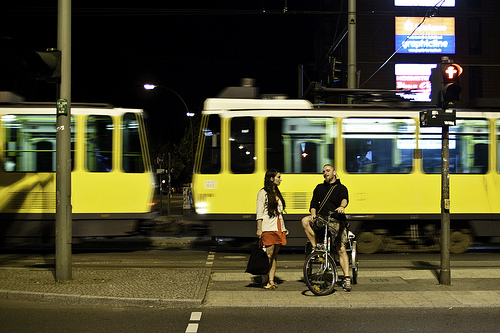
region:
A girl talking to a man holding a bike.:
[245, 163, 282, 290]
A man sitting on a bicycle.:
[300, 163, 353, 295]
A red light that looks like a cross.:
[442, 58, 462, 80]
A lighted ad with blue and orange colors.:
[392, 14, 460, 52]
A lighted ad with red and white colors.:
[390, 60, 452, 97]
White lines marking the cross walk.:
[183, 233, 223, 328]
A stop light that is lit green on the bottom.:
[327, 52, 344, 97]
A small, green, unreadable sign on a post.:
[52, 96, 71, 116]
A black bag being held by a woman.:
[242, 238, 277, 283]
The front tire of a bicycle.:
[301, 248, 344, 295]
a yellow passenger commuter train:
[186, 93, 496, 256]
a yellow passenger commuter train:
[4, 90, 156, 262]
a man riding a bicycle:
[302, 159, 360, 294]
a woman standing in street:
[246, 167, 291, 290]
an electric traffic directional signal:
[434, 55, 463, 105]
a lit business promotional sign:
[391, 13, 453, 53]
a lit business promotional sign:
[391, 62, 436, 98]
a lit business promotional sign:
[393, 0, 454, 6]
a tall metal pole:
[53, 0, 71, 283]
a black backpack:
[242, 230, 271, 277]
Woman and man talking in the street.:
[253, 165, 358, 298]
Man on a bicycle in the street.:
[301, 164, 351, 293]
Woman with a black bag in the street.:
[246, 168, 286, 288]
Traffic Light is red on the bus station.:
[431, 59, 463, 111]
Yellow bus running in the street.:
[2, 82, 499, 253]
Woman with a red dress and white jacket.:
[253, 170, 284, 292]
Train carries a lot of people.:
[1, 91, 498, 253]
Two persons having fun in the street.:
[253, 166, 353, 295]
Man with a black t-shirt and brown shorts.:
[301, 163, 353, 292]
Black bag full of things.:
[245, 236, 272, 278]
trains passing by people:
[4, 62, 485, 250]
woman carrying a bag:
[250, 220, 294, 247]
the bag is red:
[240, 221, 288, 255]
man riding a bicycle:
[290, 155, 370, 290]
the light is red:
[430, 56, 465, 86]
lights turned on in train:
[275, 110, 485, 175]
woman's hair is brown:
[250, 155, 286, 215]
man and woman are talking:
[236, 155, 359, 307]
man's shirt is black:
[293, 174, 355, 221]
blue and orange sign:
[383, 13, 463, 63]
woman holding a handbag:
[245, 169, 289, 292]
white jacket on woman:
[256, 186, 290, 236]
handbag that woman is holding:
[245, 240, 272, 277]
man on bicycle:
[299, 165, 360, 295]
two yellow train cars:
[4, 100, 496, 245]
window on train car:
[341, 118, 418, 173]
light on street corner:
[420, 58, 468, 282]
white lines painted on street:
[181, 308, 213, 331]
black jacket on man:
[309, 180, 351, 216]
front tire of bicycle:
[304, 248, 339, 293]